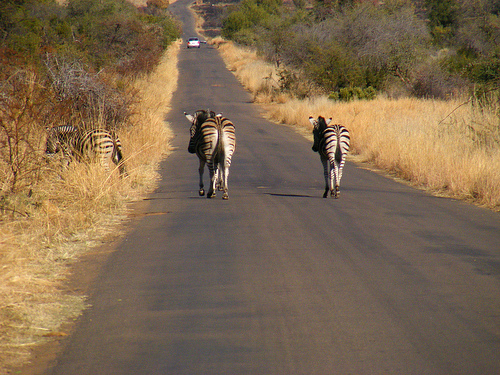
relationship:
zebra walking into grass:
[307, 115, 351, 200] [0, 30, 190, 370]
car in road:
[186, 36, 202, 49] [51, 0, 499, 375]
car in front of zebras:
[186, 36, 202, 49] [33, 104, 355, 201]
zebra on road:
[182, 109, 237, 200] [51, 0, 499, 375]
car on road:
[184, 25, 205, 53] [51, 0, 499, 375]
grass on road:
[11, 142, 130, 301] [51, 0, 499, 375]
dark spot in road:
[262, 182, 314, 206] [92, 0, 496, 374]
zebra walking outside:
[44, 124, 129, 180] [3, 1, 478, 361]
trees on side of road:
[288, 7, 466, 104] [51, 0, 499, 375]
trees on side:
[2, 0, 179, 111] [0, 1, 181, 371]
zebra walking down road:
[307, 115, 351, 200] [51, 0, 499, 375]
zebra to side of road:
[44, 124, 129, 180] [51, 0, 499, 375]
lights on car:
[184, 40, 204, 47] [182, 37, 204, 50]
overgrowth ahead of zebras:
[259, 6, 498, 103] [31, 86, 381, 205]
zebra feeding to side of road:
[34, 105, 138, 199] [67, 0, 465, 372]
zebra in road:
[309, 104, 359, 207] [108, 234, 488, 374]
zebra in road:
[172, 102, 255, 222] [108, 234, 488, 374]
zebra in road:
[44, 124, 129, 180] [108, 234, 488, 374]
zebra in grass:
[44, 124, 129, 180] [14, 182, 107, 274]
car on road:
[186, 36, 202, 49] [51, 0, 499, 375]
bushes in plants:
[326, 82, 377, 104] [296, 83, 321, 104]